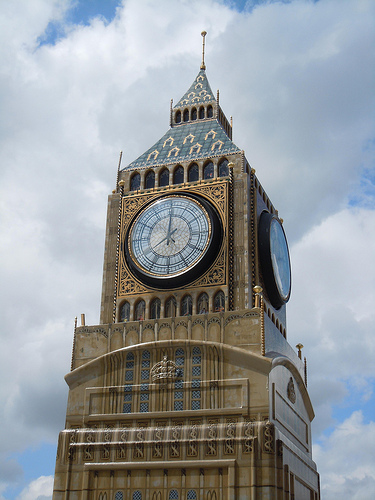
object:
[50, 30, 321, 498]
tower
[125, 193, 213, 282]
clock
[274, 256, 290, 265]
dials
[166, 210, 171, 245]
dial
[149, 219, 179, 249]
dial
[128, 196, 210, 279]
black dials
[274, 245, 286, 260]
dials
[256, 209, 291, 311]
clock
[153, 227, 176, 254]
dials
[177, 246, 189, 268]
lines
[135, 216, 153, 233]
numerals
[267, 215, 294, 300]
cover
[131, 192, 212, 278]
clock face